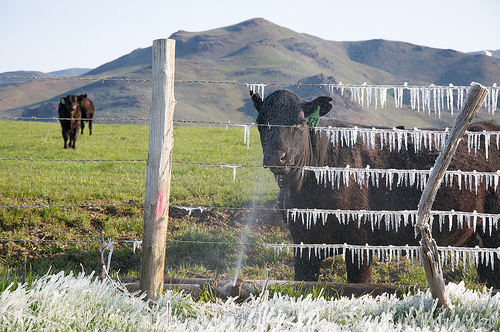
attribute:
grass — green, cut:
[30, 124, 173, 262]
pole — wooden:
[144, 32, 189, 296]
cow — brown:
[246, 83, 498, 295]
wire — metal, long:
[0, 71, 497, 90]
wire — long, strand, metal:
[11, 105, 491, 153]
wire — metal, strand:
[171, 72, 498, 102]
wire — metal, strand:
[173, 112, 498, 143]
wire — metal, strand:
[170, 155, 498, 185]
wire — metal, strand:
[167, 202, 499, 222]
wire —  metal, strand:
[163, 232, 498, 252]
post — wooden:
[128, 31, 197, 313]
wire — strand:
[248, 78, 498, 124]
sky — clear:
[27, 15, 87, 57]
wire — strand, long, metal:
[0, 238, 497, 253]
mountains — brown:
[1, 17, 498, 129]